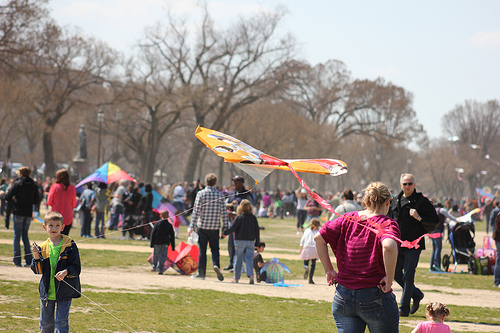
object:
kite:
[193, 123, 349, 183]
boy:
[31, 214, 84, 332]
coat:
[30, 234, 84, 298]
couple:
[187, 173, 263, 285]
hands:
[221, 228, 228, 240]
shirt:
[319, 208, 401, 290]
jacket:
[388, 190, 438, 250]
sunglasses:
[401, 181, 414, 186]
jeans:
[329, 280, 399, 332]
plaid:
[198, 187, 220, 230]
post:
[96, 112, 110, 172]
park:
[0, 150, 499, 328]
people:
[45, 169, 76, 236]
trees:
[7, 31, 132, 177]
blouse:
[297, 229, 320, 260]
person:
[150, 212, 176, 273]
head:
[161, 209, 170, 219]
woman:
[221, 197, 263, 284]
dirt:
[95, 243, 149, 251]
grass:
[98, 248, 151, 265]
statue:
[72, 124, 89, 177]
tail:
[292, 169, 441, 250]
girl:
[412, 302, 456, 331]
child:
[296, 218, 323, 283]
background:
[12, 17, 487, 195]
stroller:
[442, 219, 481, 273]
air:
[151, 110, 393, 234]